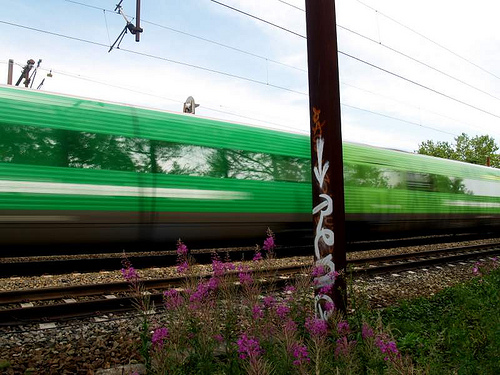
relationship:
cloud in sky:
[216, 2, 279, 38] [1, 3, 499, 173]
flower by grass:
[303, 315, 329, 334] [182, 268, 495, 363]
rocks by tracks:
[30, 274, 94, 285] [11, 235, 499, 331]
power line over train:
[0, 20, 459, 137] [6, 75, 490, 269]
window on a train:
[154, 138, 224, 178] [3, 82, 497, 258]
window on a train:
[153, 139, 225, 178] [2, 84, 495, 282]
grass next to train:
[175, 276, 497, 372] [3, 82, 497, 258]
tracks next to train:
[0, 242, 499, 303] [3, 82, 497, 258]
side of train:
[2, 94, 499, 216] [3, 82, 497, 258]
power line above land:
[0, 20, 459, 137] [7, 123, 494, 371]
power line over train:
[0, 20, 459, 137] [3, 82, 497, 258]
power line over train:
[0, 22, 309, 71] [3, 82, 497, 258]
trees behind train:
[414, 134, 484, 164] [3, 82, 497, 258]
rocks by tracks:
[346, 266, 459, 310] [0, 242, 499, 303]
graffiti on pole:
[310, 136, 336, 318] [303, 2, 347, 325]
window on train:
[153, 139, 225, 178] [0, 86, 481, 246]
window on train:
[153, 139, 225, 178] [3, 82, 497, 258]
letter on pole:
[309, 191, 331, 229] [303, 2, 347, 325]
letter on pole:
[313, 227, 334, 258] [303, 2, 347, 325]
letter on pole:
[310, 252, 334, 288] [303, 2, 347, 325]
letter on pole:
[314, 294, 335, 317] [303, 2, 347, 325]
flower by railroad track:
[303, 315, 329, 334] [135, 272, 281, 302]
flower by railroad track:
[303, 315, 329, 334] [191, 256, 314, 277]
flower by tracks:
[355, 313, 375, 341] [0, 242, 499, 303]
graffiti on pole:
[310, 136, 329, 189] [302, 110, 351, 362]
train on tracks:
[0, 84, 499, 256] [7, 215, 280, 290]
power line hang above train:
[0, 20, 459, 137] [24, 124, 242, 184]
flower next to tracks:
[303, 315, 329, 334] [105, 255, 236, 319]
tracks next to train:
[34, 225, 286, 295] [4, 104, 297, 224]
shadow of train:
[20, 198, 494, 262] [36, 144, 463, 196]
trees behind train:
[414, 132, 499, 169] [134, 162, 497, 201]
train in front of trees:
[15, 84, 282, 232] [427, 132, 484, 156]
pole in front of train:
[304, 7, 355, 320] [0, 84, 499, 256]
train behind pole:
[0, 84, 499, 256] [304, 7, 355, 320]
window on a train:
[153, 139, 225, 178] [4, 90, 292, 253]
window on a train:
[153, 139, 225, 178] [5, 92, 281, 241]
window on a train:
[153, 139, 225, 178] [4, 95, 290, 229]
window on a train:
[153, 139, 225, 178] [346, 139, 483, 237]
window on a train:
[153, 139, 225, 178] [338, 142, 482, 249]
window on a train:
[153, 139, 225, 178] [345, 143, 484, 243]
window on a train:
[153, 139, 225, 178] [345, 141, 484, 224]